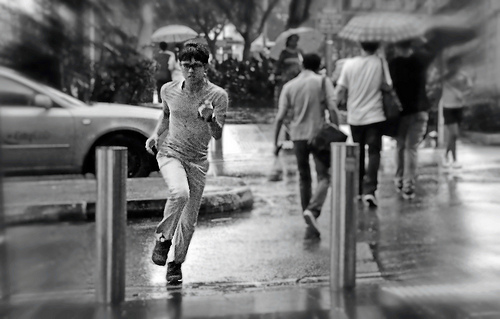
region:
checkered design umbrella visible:
[330, 9, 425, 50]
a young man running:
[146, 39, 228, 286]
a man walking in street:
[266, 49, 341, 234]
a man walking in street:
[334, 40, 393, 207]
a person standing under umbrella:
[263, 23, 322, 68]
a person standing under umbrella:
[151, 22, 198, 84]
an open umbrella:
[423, 10, 479, 48]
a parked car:
[0, 66, 164, 177]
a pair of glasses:
[177, 59, 205, 72]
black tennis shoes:
[148, 239, 173, 268]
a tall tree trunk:
[165, 260, 182, 285]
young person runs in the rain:
[142, 35, 233, 312]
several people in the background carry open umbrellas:
[141, 4, 473, 71]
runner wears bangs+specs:
[175, 35, 213, 75]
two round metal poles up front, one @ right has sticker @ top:
[83, 135, 364, 316]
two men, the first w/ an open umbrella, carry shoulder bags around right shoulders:
[274, 28, 411, 247]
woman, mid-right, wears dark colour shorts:
[423, 48, 481, 181]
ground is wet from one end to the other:
[0, 89, 499, 317]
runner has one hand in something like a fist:
[140, 97, 227, 164]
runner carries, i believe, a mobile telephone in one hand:
[134, 94, 220, 164]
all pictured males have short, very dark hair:
[170, 35, 380, 84]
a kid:
[105, 36, 297, 305]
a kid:
[165, 30, 262, 282]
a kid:
[172, 108, 239, 302]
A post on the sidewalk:
[93, 140, 138, 310]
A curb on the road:
[10, 174, 83, 225]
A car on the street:
[5, 59, 155, 179]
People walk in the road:
[270, 11, 449, 242]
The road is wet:
[418, 201, 498, 270]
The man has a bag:
[307, 67, 352, 173]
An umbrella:
[333, 7, 427, 44]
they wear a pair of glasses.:
[173, 58, 208, 71]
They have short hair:
[165, 42, 216, 92]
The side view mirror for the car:
[30, 91, 61, 113]